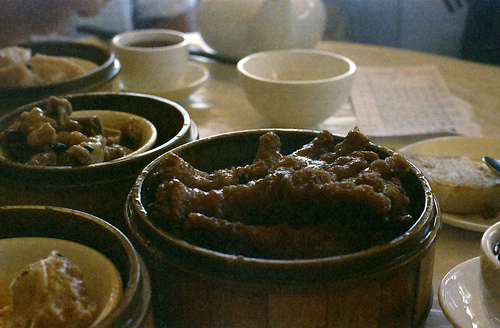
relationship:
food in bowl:
[155, 126, 414, 243] [123, 127, 434, 327]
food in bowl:
[9, 96, 141, 169] [1, 90, 200, 216]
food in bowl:
[2, 248, 98, 327] [2, 200, 155, 327]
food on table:
[155, 126, 414, 243] [1, 39, 500, 327]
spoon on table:
[485, 158, 500, 177] [1, 39, 500, 327]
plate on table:
[395, 134, 500, 229] [1, 39, 500, 327]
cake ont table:
[396, 150, 499, 216] [1, 39, 500, 327]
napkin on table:
[348, 64, 459, 135] [1, 39, 500, 327]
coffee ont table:
[111, 29, 213, 100] [1, 39, 500, 327]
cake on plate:
[412, 155, 500, 215] [395, 134, 500, 229]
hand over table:
[1, 1, 107, 46] [1, 39, 500, 327]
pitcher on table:
[196, 0, 328, 60] [1, 39, 500, 327]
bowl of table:
[237, 46, 357, 130] [1, 39, 500, 327]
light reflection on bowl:
[267, 69, 282, 80] [237, 46, 357, 130]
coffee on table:
[111, 29, 210, 95] [1, 39, 500, 327]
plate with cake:
[395, 134, 500, 229] [412, 155, 500, 215]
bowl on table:
[237, 46, 357, 130] [1, 39, 500, 327]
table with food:
[1, 39, 500, 327] [155, 126, 414, 243]